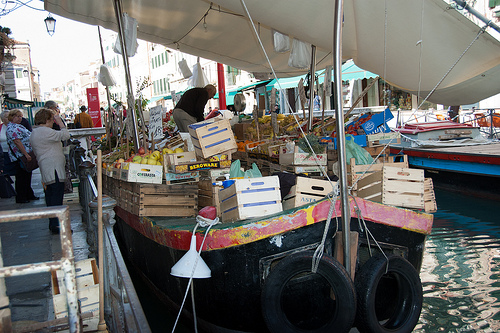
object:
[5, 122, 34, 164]
shirt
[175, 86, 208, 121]
shirt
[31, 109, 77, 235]
people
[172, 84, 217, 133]
man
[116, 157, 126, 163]
produce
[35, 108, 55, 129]
head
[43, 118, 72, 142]
arm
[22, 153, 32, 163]
hand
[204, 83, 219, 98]
head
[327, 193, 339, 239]
rope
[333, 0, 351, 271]
pole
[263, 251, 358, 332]
tires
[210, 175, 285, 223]
boxes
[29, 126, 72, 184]
shirt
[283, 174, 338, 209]
produce box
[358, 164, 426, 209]
produce box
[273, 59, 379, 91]
building awning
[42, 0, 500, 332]
boat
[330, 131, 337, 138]
fruit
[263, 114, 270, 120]
fruit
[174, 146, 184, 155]
fruit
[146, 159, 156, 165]
fruit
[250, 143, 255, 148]
fruit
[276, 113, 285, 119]
fruit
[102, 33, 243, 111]
building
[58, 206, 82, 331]
bar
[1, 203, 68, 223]
bar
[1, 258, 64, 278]
bar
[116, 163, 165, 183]
box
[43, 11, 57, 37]
lamp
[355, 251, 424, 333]
tire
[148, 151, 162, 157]
apple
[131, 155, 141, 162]
apple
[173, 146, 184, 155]
apple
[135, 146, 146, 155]
apple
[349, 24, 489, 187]
string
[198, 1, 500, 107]
canopy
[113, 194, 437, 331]
paint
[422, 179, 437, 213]
fruit crate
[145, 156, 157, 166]
apple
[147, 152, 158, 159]
apple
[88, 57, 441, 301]
produce market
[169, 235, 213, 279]
funnel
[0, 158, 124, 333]
dock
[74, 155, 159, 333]
railing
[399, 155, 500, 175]
stripes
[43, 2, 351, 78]
awnings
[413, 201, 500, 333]
water